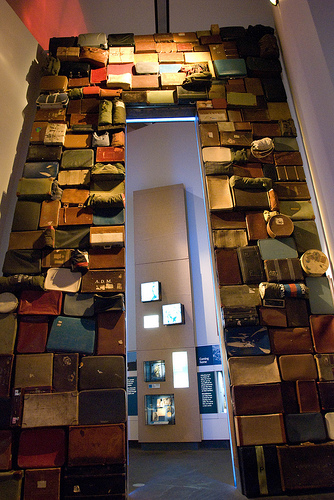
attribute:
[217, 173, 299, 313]
wallets — many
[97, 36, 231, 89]
wallets — several 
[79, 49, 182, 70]
wallet — blue ,  red ones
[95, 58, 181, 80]
wallet —  red ,  blue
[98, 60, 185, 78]
wallet —  green , red  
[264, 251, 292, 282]
wallet — green 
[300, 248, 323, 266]
box — circle 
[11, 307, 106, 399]
wallets — two red , together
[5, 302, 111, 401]
wallets — green , blue 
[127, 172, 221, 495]
frames — two picture 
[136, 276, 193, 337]
wallet — white 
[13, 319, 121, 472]
pouches — wall 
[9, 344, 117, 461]
pouches — wall 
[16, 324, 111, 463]
pouches — wall 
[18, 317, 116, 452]
pouches — wall 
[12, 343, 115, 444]
pouches — wall 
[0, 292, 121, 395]
pouches — wall 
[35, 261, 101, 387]
pouches — wall 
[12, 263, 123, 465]
pouches — wall 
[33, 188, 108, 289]
pouches — wall 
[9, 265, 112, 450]
pouches — wall 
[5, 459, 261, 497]
writing — white 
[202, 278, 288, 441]
writing — white 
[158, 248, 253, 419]
writing — white 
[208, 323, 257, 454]
writing — white 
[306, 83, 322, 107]
bricks — big 